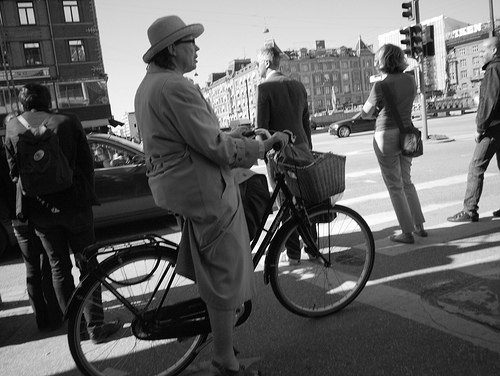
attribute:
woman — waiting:
[352, 60, 429, 244]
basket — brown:
[268, 143, 351, 205]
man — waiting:
[429, 43, 498, 218]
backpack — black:
[23, 107, 61, 195]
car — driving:
[0, 136, 146, 243]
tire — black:
[257, 217, 383, 319]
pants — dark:
[41, 218, 126, 335]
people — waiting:
[363, 25, 495, 255]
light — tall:
[400, 1, 439, 140]